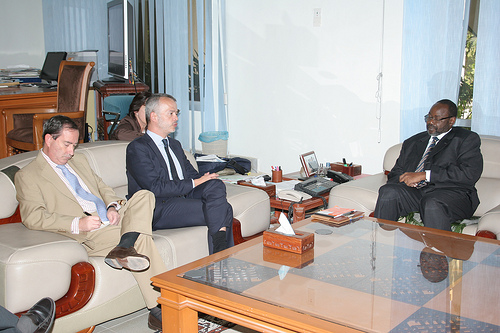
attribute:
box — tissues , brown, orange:
[263, 211, 316, 254]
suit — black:
[373, 127, 483, 240]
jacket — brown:
[12, 148, 126, 246]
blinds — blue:
[143, 0, 228, 152]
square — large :
[150, 210, 499, 332]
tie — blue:
[53, 163, 111, 221]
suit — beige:
[17, 145, 170, 309]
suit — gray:
[124, 132, 236, 255]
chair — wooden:
[1, 57, 98, 163]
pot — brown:
[271, 168, 283, 182]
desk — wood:
[0, 68, 87, 152]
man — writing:
[16, 113, 177, 330]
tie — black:
[157, 137, 182, 183]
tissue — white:
[275, 211, 292, 233]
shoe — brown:
[104, 243, 155, 273]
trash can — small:
[194, 131, 230, 163]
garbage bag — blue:
[192, 122, 231, 144]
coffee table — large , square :
[149, 200, 498, 330]